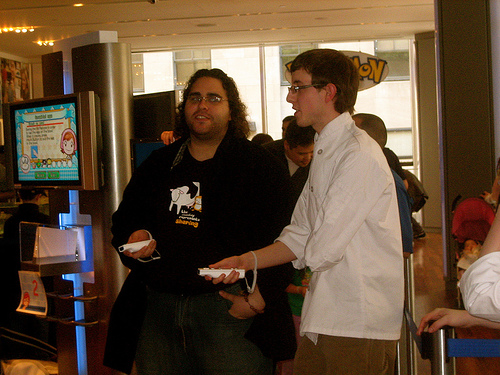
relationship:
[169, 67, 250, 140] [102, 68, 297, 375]
hair on guy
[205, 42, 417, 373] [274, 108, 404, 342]
fella wearing shirt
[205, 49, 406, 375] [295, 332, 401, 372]
fella wearing pants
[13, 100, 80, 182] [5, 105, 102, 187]
screen belonging to television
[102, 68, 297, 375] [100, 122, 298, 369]
guy wearing clothing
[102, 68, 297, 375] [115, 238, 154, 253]
guy holding controller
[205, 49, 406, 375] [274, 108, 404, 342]
fella wearing shirt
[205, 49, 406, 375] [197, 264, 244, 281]
fella holding controller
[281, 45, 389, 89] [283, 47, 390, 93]
pokeman logo painted on sign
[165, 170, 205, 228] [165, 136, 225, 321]
cow pressed on shirt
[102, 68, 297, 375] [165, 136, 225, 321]
guy wearing shirt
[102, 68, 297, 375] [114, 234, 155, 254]
guy holding wii remote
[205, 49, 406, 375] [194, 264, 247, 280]
fella holding wii remote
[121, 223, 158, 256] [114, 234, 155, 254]
hand holding wii remote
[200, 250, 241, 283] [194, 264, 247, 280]
hand holding wii remote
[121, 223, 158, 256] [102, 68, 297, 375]
hand belonging to guy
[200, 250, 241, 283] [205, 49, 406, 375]
hand belonging to fella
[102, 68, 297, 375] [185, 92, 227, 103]
guy wearing glasses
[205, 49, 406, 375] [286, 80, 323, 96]
fella wearing glasses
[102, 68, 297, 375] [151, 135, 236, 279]
guy wearing shirt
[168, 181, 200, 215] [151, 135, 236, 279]
cow printed on shirt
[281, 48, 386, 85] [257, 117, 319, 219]
pokeman logo hanging behind man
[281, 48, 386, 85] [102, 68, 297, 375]
pokeman logo hanging behind guy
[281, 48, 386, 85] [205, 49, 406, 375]
pokeman logo hanging behind fella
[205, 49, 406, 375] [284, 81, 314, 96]
fella wearing glasses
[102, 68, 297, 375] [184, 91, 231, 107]
guy wearing eyeglasses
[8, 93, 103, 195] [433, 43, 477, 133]
tv hanging on wall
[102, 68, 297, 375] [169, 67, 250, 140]
guy has hair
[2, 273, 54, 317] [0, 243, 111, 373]
flyer on shelf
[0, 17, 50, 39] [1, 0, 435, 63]
lights are on ceiling